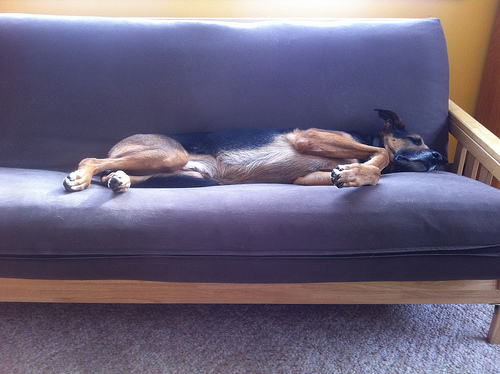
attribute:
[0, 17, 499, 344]
couch — wooden, wood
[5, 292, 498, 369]
carpet — beige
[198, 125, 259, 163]
fur — black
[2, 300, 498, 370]
carpet — berber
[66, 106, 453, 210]
dog — black, brown, white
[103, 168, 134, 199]
paw — black, brown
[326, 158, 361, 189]
paw — black, brown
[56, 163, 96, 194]
paw — black, brown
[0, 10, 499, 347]
sofa — purple, leather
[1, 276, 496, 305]
frame — wooden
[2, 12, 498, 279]
cushion — purple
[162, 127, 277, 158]
spot — black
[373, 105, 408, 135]
ear — sticking up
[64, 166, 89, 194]
paw — black, brown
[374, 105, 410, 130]
ear — black